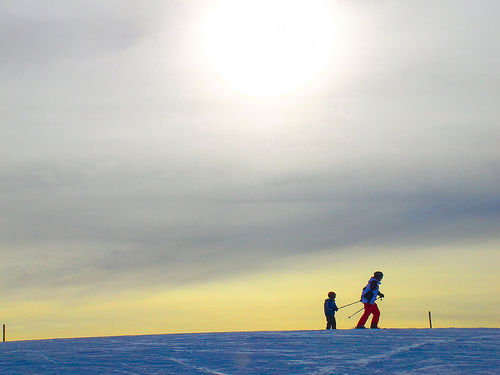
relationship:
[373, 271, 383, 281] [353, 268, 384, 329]
helmet on adult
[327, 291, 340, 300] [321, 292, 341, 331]
helmet on child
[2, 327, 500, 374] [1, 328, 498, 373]
snow on ground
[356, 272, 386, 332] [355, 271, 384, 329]
glove on adult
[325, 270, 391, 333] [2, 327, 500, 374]
people in snow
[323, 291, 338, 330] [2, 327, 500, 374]
child in snow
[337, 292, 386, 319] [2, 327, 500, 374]
pole in snow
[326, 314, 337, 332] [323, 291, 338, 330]
pants on child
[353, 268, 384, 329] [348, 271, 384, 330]
adult wearing helmet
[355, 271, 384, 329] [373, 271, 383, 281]
adult wearing helmet